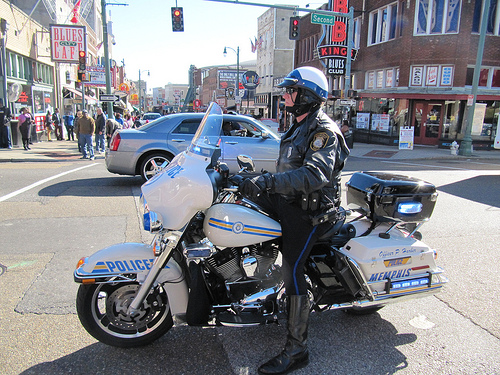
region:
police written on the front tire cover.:
[80, 239, 187, 279]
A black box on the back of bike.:
[343, 167, 444, 222]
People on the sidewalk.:
[36, 87, 139, 152]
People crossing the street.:
[73, 103, 119, 155]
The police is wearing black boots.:
[259, 281, 331, 366]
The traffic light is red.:
[259, 1, 318, 40]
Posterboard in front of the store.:
[390, 122, 425, 163]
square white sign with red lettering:
[48, 20, 88, 64]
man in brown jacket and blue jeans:
[73, 110, 98, 161]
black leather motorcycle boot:
[257, 288, 317, 373]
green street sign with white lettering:
[311, 7, 337, 27]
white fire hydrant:
[448, 137, 460, 157]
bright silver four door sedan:
[107, 113, 285, 180]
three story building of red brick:
[291, 0, 498, 145]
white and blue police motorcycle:
[58, 99, 449, 349]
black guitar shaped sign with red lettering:
[316, 1, 360, 78]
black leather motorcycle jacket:
[256, 108, 354, 212]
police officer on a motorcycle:
[72, 64, 454, 373]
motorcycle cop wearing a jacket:
[226, 65, 351, 374]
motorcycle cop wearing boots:
[237, 67, 362, 374]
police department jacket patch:
[306, 129, 331, 153]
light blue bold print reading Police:
[104, 258, 154, 273]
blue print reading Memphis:
[368, 268, 412, 283]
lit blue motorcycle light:
[398, 201, 424, 214]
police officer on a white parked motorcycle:
[71, 63, 448, 373]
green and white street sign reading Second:
[308, 11, 335, 26]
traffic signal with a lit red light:
[170, 6, 185, 31]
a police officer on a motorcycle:
[50, 80, 448, 324]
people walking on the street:
[16, 79, 156, 169]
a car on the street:
[113, 90, 306, 180]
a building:
[297, 18, 481, 132]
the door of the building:
[413, 98, 443, 143]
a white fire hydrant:
[449, 135, 458, 152]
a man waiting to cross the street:
[70, 104, 95, 156]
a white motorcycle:
[76, 116, 445, 340]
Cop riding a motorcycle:
[232, 66, 349, 373]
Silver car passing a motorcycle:
[105, 111, 280, 178]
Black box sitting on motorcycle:
[345, 169, 437, 221]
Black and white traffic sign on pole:
[96, 94, 121, 101]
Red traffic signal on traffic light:
[172, 8, 180, 18]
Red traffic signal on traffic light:
[290, 15, 299, 26]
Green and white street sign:
[307, 13, 337, 26]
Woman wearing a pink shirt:
[12, 107, 34, 152]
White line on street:
[0, 158, 103, 213]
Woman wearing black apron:
[15, 105, 34, 150]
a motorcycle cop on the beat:
[207, 63, 349, 373]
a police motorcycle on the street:
[72, 100, 447, 347]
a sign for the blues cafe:
[49, 23, 85, 63]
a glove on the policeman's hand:
[235, 169, 264, 194]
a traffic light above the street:
[167, 10, 185, 35]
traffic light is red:
[170, 5, 184, 32]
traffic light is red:
[288, 15, 302, 39]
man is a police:
[244, 66, 351, 373]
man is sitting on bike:
[237, 62, 351, 373]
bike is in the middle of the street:
[74, 102, 448, 348]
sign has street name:
[309, 11, 334, 25]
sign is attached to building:
[49, 21, 87, 65]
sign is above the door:
[409, 64, 456, 89]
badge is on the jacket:
[309, 129, 329, 151]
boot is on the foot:
[256, 292, 313, 373]